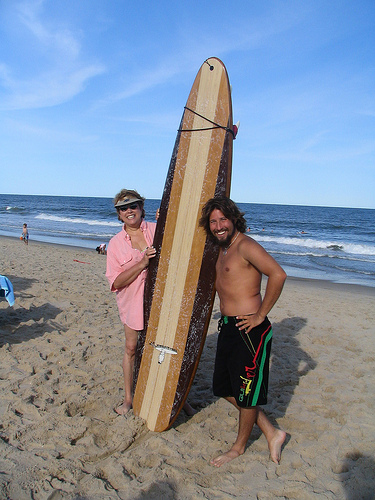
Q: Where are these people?
A: At the beach.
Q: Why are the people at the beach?
A: To surf.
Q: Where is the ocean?
A: Behind the surfer.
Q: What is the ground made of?
A: The ground is sand.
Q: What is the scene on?
A: The beach.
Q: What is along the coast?
A: The setting.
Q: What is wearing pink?
A: The woman.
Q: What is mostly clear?
A: The weather.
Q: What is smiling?
A: Both people.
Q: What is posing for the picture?
A: Two people.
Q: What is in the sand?
A: The foot prints.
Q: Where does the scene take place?
A: At the beach.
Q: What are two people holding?
A: A surfboard.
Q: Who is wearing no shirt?
A: Man on the right.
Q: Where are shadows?
A: On the sand.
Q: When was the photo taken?
A: During the daytime.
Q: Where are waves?
A: In the ocean.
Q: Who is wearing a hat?
A: Woman on left.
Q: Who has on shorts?
A: The man.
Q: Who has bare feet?
A: Both people.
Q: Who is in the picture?
A: A woman and man.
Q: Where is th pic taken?
A: A beach.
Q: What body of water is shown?
A: An ocean.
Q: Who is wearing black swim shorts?
A: A man.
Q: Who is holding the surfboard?
A: A man and woman.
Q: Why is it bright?
A: Sunny.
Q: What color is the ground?
A: Brown.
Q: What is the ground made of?
A: Sand.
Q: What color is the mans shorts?
A: Black.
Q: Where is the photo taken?
A: At a beach.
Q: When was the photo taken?
A: Daytime.